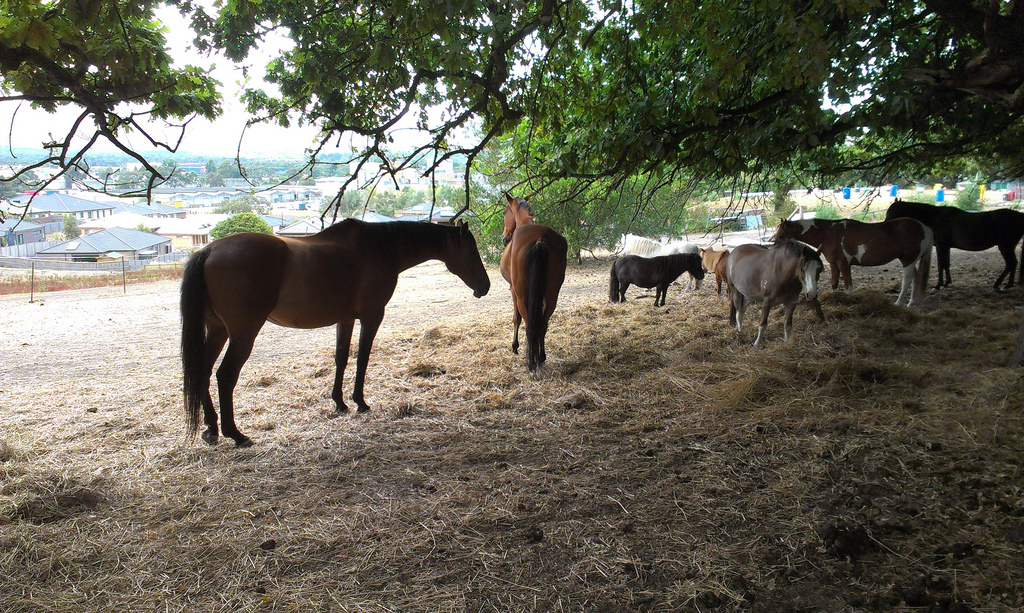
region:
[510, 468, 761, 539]
hay on the ground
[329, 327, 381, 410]
front legs on the horse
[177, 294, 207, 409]
the horses tail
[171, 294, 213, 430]
the tail is black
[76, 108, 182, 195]
a tree branch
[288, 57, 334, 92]
leaves are green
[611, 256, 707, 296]
a brown horse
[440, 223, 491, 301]
the horses head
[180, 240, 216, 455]
A black tail of a horse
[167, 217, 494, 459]
A brown horse standing on hay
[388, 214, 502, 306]
Head and neck of a horse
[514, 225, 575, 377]
The behind and tail of a horse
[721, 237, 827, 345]
A small brown horse with white patch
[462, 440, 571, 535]
A patch of hay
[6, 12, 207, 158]
Branches with lots of leaves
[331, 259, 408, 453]
front legs of a horse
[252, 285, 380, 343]
Belly and abdomen of a horse.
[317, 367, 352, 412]
leg of the horse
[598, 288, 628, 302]
leg of the horse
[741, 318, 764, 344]
leg of the horse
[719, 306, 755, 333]
leg of the horse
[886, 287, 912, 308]
leg of the horse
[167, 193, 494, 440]
a brown horse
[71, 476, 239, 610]
hay on the ground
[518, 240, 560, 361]
tail on the horse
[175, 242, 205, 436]
tail on the horse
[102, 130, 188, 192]
branch on the tree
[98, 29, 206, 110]
leaves on the tree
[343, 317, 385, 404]
leg on the horse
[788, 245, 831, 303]
head on the animal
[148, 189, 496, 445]
standing brown and black colored horse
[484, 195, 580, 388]
standing brown and black colored horse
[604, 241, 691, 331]
standing brown and black colored horse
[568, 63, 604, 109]
green leaves in brown tree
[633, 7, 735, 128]
green leaves in brown tree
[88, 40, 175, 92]
green leaves in brown tree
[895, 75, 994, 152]
green leaves in brown tree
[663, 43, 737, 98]
green leaves in brown tree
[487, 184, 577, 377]
a brown and black horse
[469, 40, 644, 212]
green tree leaves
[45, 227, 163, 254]
the roof of a building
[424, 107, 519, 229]
a large tree branch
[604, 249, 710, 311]
a large black horse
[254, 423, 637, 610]
a section of hay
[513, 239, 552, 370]
a black horse tail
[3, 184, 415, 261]
roof tops of houses down below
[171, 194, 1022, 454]
herd of horses under a tree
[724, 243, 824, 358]
horse with a white blaze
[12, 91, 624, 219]
leaves have been eaten off ends of branches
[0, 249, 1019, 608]
dry dead grass covers the ground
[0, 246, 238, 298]
fence and posts at edge of pasture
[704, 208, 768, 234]
top of a truck parked in the distance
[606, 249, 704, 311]
an all black horse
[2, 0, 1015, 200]
tree branches forming a canopy.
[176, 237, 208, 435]
long black tail on a brown horse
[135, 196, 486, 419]
An animal in a field.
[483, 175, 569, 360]
An animal in a field.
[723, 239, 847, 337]
An animal in a field.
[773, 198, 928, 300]
An animal in a field.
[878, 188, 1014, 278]
An animal in a field.